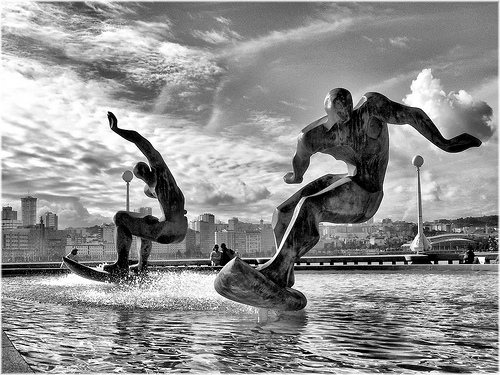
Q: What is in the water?
A: Statues.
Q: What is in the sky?
A: Clouds.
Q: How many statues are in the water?
A: Two.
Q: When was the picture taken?
A: Daytime.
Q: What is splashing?
A: Water.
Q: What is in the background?
A: Buildings.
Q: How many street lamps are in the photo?
A: Two.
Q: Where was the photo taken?
A: In a large city, near sculptures.